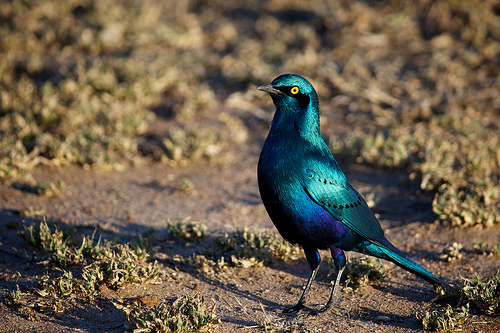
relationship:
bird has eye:
[253, 72, 441, 318] [291, 86, 301, 94]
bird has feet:
[253, 72, 441, 318] [275, 264, 344, 319]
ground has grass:
[0, 1, 499, 333] [1, 1, 499, 333]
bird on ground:
[253, 72, 441, 318] [0, 1, 499, 333]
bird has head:
[253, 72, 441, 318] [254, 72, 320, 123]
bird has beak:
[253, 72, 441, 318] [258, 83, 279, 94]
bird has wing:
[253, 72, 441, 318] [297, 151, 412, 266]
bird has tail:
[253, 72, 441, 318] [359, 241, 447, 291]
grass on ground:
[1, 1, 499, 333] [0, 1, 499, 333]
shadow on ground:
[0, 207, 295, 316] [0, 1, 499, 333]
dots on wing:
[307, 173, 362, 211] [297, 151, 412, 266]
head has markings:
[254, 72, 320, 123] [275, 83, 311, 109]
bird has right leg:
[253, 72, 441, 318] [284, 246, 322, 317]